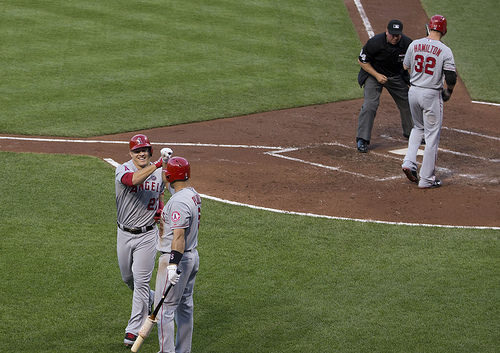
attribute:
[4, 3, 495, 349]
field — green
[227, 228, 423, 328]
grass — green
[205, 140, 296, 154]
line — white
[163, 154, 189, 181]
helmet — red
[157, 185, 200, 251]
jersey — gray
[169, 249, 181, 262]
band — black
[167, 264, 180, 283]
glove — white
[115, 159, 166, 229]
jersey — gray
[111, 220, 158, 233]
belt — black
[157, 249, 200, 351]
pants — grey, gray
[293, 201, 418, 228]
line — white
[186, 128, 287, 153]
line — white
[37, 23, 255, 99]
grass — green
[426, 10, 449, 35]
helmet — red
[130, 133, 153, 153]
helmet — red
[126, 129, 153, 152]
helmet — red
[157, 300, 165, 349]
stripe — red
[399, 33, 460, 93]
shirt — gray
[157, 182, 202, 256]
shirt — gray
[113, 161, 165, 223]
shirt — gray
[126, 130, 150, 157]
helmet — red, hard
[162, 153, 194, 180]
helmet — red, hard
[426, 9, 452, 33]
helmet — red, hard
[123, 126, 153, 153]
helmet — hard, red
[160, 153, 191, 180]
helmet — hard, red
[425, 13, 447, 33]
helmet — hard, red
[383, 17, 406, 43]
hat — black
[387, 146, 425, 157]
base — white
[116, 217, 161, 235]
belt — black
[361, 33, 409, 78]
shirt — black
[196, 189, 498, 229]
line — white